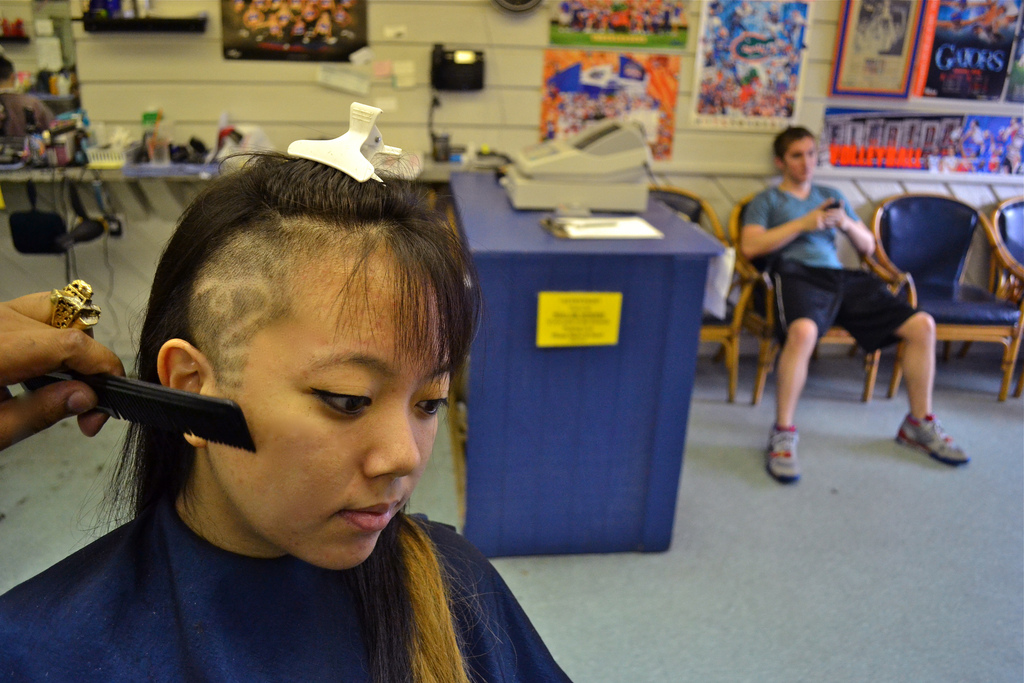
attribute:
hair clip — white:
[285, 100, 385, 181]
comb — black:
[60, 360, 261, 460]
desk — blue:
[447, 162, 715, 552]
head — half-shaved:
[127, 147, 458, 575]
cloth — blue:
[4, 509, 569, 680]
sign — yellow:
[536, 289, 621, 348]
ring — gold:
[41, 274, 100, 326]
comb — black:
[26, 360, 256, 449]